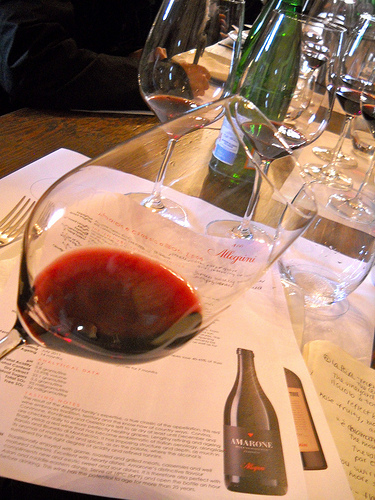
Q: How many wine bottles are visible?
A: One.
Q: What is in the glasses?
A: Wine.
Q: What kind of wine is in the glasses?
A: Red wine.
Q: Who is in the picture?
A: No one.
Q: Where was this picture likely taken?
A: Wine tasting.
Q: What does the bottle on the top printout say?
A: Amarone.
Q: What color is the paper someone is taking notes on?
A: Yellow.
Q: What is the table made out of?
A: Wood.